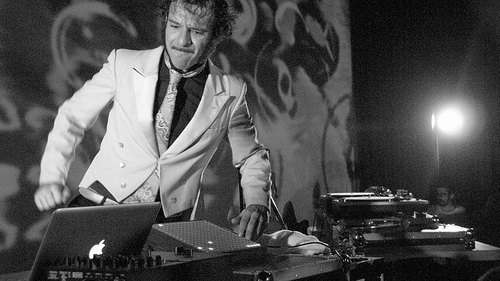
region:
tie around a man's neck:
[144, 46, 211, 160]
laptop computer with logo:
[4, 194, 164, 280]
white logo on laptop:
[85, 230, 110, 266]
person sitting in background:
[426, 180, 466, 217]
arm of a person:
[223, 74, 274, 243]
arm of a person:
[26, 48, 126, 214]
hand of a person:
[32, 179, 74, 214]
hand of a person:
[227, 202, 276, 242]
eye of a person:
[189, 23, 206, 39]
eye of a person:
[167, 22, 182, 32]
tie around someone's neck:
[141, 44, 210, 154]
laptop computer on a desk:
[17, 196, 164, 280]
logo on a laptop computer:
[87, 234, 107, 261]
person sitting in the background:
[427, 180, 465, 218]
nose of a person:
[172, 31, 195, 48]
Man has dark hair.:
[206, 11, 238, 51]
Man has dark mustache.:
[166, 40, 205, 60]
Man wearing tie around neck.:
[149, 68, 202, 128]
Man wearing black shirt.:
[186, 95, 196, 114]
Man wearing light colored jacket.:
[106, 105, 152, 152]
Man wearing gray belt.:
[71, 181, 108, 206]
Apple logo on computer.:
[78, 230, 117, 263]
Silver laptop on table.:
[36, 207, 161, 261]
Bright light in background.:
[428, 105, 488, 165]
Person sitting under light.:
[428, 183, 453, 212]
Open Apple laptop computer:
[29, 200, 162, 280]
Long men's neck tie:
[153, 57, 206, 157]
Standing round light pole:
[424, 97, 471, 177]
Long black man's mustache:
[167, 44, 198, 58]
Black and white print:
[276, 7, 345, 154]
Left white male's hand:
[226, 202, 274, 244]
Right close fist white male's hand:
[31, 177, 73, 211]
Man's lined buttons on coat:
[111, 137, 126, 187]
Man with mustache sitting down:
[425, 180, 466, 225]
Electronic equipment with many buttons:
[43, 240, 234, 277]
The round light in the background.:
[435, 101, 476, 146]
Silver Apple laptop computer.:
[27, 196, 151, 271]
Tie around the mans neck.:
[159, 58, 187, 140]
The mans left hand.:
[226, 200, 264, 235]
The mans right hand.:
[26, 183, 66, 210]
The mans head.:
[154, 5, 226, 74]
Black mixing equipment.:
[61, 251, 233, 279]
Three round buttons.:
[111, 141, 134, 193]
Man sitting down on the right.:
[434, 185, 464, 220]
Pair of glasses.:
[439, 191, 448, 198]